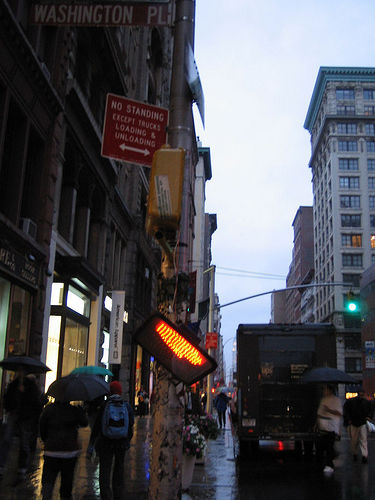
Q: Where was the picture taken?
A: In a city.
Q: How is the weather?
A: Raining.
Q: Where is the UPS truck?
A: On the street.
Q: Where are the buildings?
A: On either side of the street.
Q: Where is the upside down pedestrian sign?
A: Hanging from the pole.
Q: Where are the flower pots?
A: Along the sidewalk.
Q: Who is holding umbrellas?
A: Pedestrians.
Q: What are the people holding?
A: Umbrellas.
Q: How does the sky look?
A: Gray and cloudy.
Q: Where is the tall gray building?
A: To the right.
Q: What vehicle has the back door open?
A: The UPS truck.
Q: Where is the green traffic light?
A: In front of the gray building.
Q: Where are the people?
A: In a city.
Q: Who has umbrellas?
A: A few people.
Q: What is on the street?
A: A truck.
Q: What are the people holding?
A: Umbrellas.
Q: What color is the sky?
A: Blue.